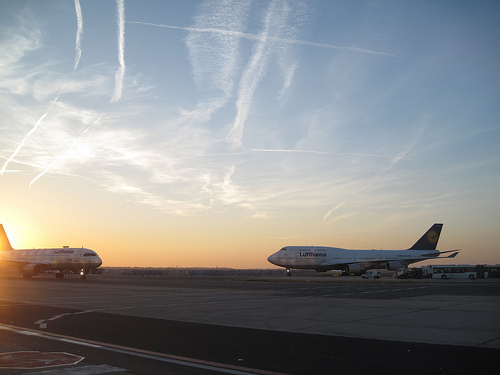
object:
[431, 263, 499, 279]
bus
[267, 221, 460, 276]
airliner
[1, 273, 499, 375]
cement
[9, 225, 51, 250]
light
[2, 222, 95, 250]
airplane/sunrise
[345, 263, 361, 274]
side engines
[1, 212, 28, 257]
sun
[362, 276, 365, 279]
wheels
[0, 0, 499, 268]
sky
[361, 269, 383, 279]
vehicle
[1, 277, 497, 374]
runway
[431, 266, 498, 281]
shuttle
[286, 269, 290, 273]
lights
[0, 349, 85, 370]
symbol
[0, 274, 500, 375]
paved ground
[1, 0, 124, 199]
smoke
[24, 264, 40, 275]
engine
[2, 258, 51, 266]
wing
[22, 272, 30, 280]
back wheels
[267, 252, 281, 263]
nose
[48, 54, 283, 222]
clouds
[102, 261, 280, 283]
trees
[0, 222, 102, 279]
airplane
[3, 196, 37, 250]
sunrise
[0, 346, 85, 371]
painting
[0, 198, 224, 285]
sunset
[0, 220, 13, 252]
tail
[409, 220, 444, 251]
tail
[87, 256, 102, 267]
nose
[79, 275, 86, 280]
front wheels